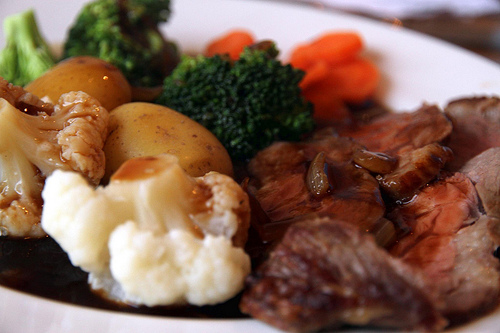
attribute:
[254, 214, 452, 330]
beef — cooked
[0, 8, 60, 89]
broccoli — green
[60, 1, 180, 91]
broccoli — green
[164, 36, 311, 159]
broccoli — green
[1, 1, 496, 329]
plate — white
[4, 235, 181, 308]
sauce — brown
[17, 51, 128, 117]
potato — small, brown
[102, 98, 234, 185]
potato — brown, small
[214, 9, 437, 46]
plate — white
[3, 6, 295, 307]
vegetables — mixed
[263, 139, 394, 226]
steak — cooked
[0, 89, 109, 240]
cauliflower — gravy smothered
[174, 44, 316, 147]
broccoli — green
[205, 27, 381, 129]
carrots — sliced